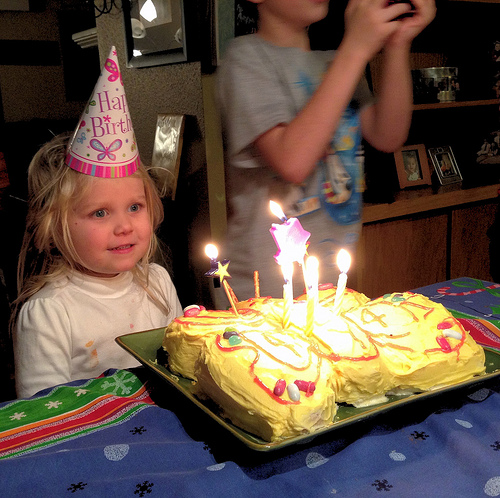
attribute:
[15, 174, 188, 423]
person — taking, wearing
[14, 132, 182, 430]
girl — wearing, smiling, wearig, open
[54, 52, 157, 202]
hat — white, birthda, pink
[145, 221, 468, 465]
cake — birthday, yellow, birthda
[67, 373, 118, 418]
platter — green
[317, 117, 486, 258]
picture — shelf, frame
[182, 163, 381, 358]
candle — lit, fire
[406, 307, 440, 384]
icing — yellow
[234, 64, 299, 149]
shirt — gra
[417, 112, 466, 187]
frame — silver, picture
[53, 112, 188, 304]
child — about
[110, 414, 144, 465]
cloth — blue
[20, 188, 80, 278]
hair — blonde